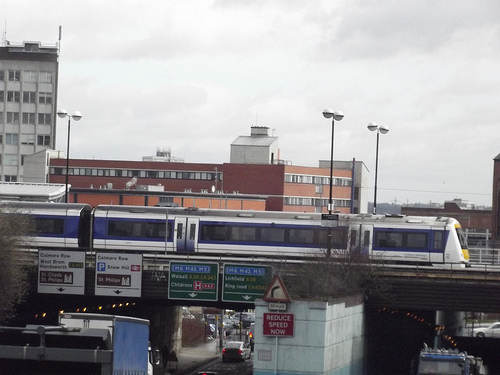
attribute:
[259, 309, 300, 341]
sign — red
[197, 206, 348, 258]
train — yellow, blue, white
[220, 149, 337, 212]
building — red, brick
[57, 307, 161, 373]
van — white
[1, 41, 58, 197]
building — tall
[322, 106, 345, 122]
lights — off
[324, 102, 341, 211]
post — black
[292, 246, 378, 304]
trees — dead, bare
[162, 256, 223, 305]
sign — green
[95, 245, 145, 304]
sign — white, large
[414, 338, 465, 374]
truck — large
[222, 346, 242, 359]
lights — on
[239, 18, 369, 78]
sky — gray, cloudy, overcast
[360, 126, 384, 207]
posts — tall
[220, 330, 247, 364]
car — silver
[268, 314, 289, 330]
text — white